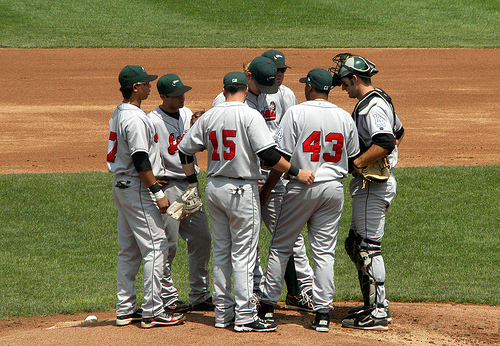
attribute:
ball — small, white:
[84, 313, 99, 326]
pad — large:
[345, 231, 356, 265]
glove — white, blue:
[114, 180, 135, 189]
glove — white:
[169, 185, 203, 221]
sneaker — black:
[141, 309, 188, 327]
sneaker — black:
[114, 316, 138, 324]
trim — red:
[173, 316, 178, 327]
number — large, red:
[303, 129, 345, 163]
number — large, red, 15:
[206, 129, 237, 163]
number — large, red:
[169, 131, 182, 157]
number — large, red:
[110, 127, 118, 171]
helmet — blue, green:
[330, 52, 378, 83]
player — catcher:
[331, 54, 405, 330]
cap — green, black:
[120, 67, 160, 88]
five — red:
[219, 129, 238, 159]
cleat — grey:
[235, 317, 277, 333]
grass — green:
[1, 1, 499, 318]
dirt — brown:
[3, 47, 499, 344]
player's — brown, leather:
[351, 158, 391, 192]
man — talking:
[213, 55, 314, 311]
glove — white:
[231, 186, 246, 198]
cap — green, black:
[299, 67, 334, 93]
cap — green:
[251, 57, 279, 95]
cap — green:
[224, 70, 248, 90]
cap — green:
[158, 73, 191, 97]